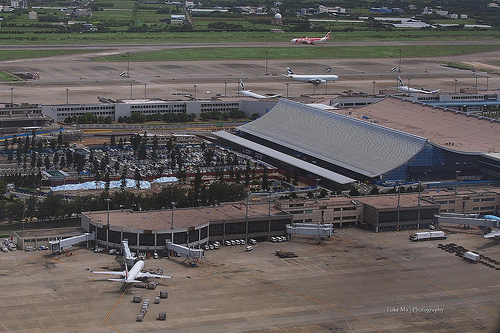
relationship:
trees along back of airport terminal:
[1, 181, 251, 228] [32, 179, 499, 277]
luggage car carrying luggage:
[133, 299, 154, 326] [142, 299, 148, 308]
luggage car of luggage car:
[134, 308, 150, 321] [134, 308, 150, 321]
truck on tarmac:
[406, 227, 448, 240] [0, 229, 499, 330]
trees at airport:
[4, 130, 75, 173] [1, 2, 494, 329]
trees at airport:
[110, 128, 164, 162] [1, 2, 494, 329]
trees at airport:
[164, 148, 219, 168] [1, 2, 494, 329]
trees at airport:
[0, 185, 250, 218] [1, 2, 494, 329]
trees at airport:
[201, 19, 258, 34] [1, 2, 494, 329]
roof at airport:
[240, 92, 498, 189] [206, 89, 498, 190]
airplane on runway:
[92, 258, 173, 282] [24, 289, 424, 326]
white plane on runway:
[278, 63, 338, 85] [10, 78, 269, 93]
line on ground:
[86, 289, 140, 321] [262, 274, 400, 301]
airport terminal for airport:
[0, 93, 498, 126] [63, 106, 223, 144]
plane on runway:
[289, 30, 331, 45] [0, 37, 498, 49]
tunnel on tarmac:
[283, 220, 335, 245] [0, 229, 499, 330]